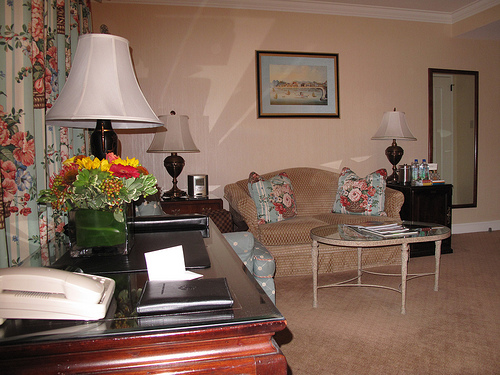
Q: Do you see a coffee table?
A: Yes, there is a coffee table.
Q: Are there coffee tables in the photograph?
A: Yes, there is a coffee table.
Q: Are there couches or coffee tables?
A: Yes, there is a coffee table.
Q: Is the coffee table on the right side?
A: Yes, the coffee table is on the right of the image.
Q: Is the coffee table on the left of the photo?
A: No, the coffee table is on the right of the image.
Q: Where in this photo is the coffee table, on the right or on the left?
A: The coffee table is on the right of the image.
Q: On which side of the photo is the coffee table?
A: The coffee table is on the right of the image.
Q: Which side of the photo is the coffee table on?
A: The coffee table is on the right of the image.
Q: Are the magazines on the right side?
A: Yes, the magazines are on the right of the image.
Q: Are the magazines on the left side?
A: No, the magazines are on the right of the image.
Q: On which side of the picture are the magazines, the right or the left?
A: The magazines are on the right of the image.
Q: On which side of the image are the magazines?
A: The magazines are on the right of the image.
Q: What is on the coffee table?
A: The magazines are on the coffee table.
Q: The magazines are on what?
A: The magazines are on the coffee table.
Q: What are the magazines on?
A: The magazines are on the coffee table.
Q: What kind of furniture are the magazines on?
A: The magazines are on the coffee table.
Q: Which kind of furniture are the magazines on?
A: The magazines are on the coffee table.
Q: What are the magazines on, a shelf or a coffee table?
A: The magazines are on a coffee table.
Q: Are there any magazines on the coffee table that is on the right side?
A: Yes, there are magazines on the coffee table.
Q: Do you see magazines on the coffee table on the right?
A: Yes, there are magazines on the coffee table.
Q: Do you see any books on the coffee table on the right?
A: No, there are magazines on the coffee table.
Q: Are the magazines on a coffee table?
A: Yes, the magazines are on a coffee table.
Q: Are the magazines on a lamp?
A: No, the magazines are on a coffee table.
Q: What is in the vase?
A: The flower is in the vase.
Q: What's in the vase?
A: The flower is in the vase.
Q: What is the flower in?
A: The flower is in the vase.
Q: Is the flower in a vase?
A: Yes, the flower is in a vase.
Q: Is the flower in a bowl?
A: No, the flower is in a vase.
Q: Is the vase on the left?
A: Yes, the vase is on the left of the image.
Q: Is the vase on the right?
A: No, the vase is on the left of the image.